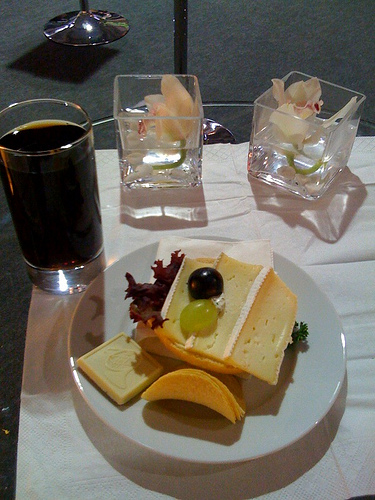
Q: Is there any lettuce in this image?
A: Yes, there is lettuce.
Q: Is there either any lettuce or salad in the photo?
A: Yes, there is lettuce.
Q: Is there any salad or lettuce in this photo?
A: Yes, there is lettuce.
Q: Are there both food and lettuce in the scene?
A: Yes, there are both lettuce and food.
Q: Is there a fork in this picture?
A: No, there are no forks.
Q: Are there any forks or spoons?
A: No, there are no forks or spoons.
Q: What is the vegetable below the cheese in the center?
A: The vegetable is lettuce.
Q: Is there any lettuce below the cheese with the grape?
A: Yes, there is lettuce below the cheese.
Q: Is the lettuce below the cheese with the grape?
A: Yes, the lettuce is below the cheese.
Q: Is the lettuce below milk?
A: No, the lettuce is below the cheese.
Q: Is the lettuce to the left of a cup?
A: No, the lettuce is to the left of the grape.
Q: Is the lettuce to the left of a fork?
A: No, the lettuce is to the left of the grape.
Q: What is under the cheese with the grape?
A: The lettuce is under the cheese.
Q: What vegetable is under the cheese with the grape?
A: The vegetable is lettuce.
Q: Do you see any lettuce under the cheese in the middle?
A: Yes, there is lettuce under the cheese.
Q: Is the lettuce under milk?
A: No, the lettuce is under the cheese.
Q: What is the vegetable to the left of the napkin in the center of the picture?
A: The vegetable is lettuce.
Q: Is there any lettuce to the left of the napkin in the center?
A: Yes, there is lettuce to the left of the napkin.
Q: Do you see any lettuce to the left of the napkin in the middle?
A: Yes, there is lettuce to the left of the napkin.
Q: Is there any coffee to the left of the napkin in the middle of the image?
A: No, there is lettuce to the left of the napkin.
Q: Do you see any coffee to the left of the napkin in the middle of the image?
A: No, there is lettuce to the left of the napkin.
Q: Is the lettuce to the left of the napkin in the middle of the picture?
A: Yes, the lettuce is to the left of the napkin.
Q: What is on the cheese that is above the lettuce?
A: The grape is on the cheese.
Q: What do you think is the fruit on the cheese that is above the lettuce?
A: The fruit is a grape.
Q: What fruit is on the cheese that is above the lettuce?
A: The fruit is a grape.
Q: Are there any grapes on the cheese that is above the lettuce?
A: Yes, there is a grape on the cheese.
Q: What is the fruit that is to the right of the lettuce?
A: The fruit is a grape.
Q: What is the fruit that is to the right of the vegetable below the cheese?
A: The fruit is a grape.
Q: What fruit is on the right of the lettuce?
A: The fruit is a grape.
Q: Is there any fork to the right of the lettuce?
A: No, there is a grape to the right of the lettuce.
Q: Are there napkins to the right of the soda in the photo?
A: Yes, there is a napkin to the right of the soda.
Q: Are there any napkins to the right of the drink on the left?
A: Yes, there is a napkin to the right of the soda.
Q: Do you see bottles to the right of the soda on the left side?
A: No, there is a napkin to the right of the soda.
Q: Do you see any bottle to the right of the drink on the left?
A: No, there is a napkin to the right of the soda.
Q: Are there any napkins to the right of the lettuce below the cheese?
A: Yes, there is a napkin to the right of the lettuce.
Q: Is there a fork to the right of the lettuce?
A: No, there is a napkin to the right of the lettuce.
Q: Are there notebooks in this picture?
A: No, there are no notebooks.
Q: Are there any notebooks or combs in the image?
A: No, there are no notebooks or combs.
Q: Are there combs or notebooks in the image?
A: No, there are no notebooks or combs.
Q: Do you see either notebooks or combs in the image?
A: No, there are no notebooks or combs.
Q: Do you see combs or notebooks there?
A: No, there are no notebooks or combs.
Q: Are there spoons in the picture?
A: No, there are no spoons.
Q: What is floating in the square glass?
A: The flower is floating in the glass.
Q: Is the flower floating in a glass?
A: Yes, the flower is floating in a glass.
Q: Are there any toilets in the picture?
A: No, there are no toilets.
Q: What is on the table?
A: The napkin is on the table.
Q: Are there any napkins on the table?
A: Yes, there is a napkin on the table.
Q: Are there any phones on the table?
A: No, there is a napkin on the table.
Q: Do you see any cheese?
A: Yes, there is cheese.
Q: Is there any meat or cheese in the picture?
A: Yes, there is cheese.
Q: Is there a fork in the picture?
A: No, there are no forks.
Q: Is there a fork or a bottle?
A: No, there are no forks or bottles.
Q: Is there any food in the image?
A: Yes, there is food.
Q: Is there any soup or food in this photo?
A: Yes, there is food.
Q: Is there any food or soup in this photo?
A: Yes, there is food.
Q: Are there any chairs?
A: No, there are no chairs.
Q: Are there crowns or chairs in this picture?
A: No, there are no chairs or crowns.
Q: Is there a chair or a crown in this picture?
A: No, there are no chairs or crowns.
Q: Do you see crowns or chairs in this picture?
A: No, there are no chairs or crowns.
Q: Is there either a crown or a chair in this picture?
A: No, there are no chairs or crowns.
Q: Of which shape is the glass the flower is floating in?
A: The glass is square.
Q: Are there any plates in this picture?
A: Yes, there is a plate.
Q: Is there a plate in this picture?
A: Yes, there is a plate.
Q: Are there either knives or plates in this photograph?
A: Yes, there is a plate.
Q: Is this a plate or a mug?
A: This is a plate.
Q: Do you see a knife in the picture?
A: No, there are no knives.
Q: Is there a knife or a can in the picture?
A: No, there are no knives or cans.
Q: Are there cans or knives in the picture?
A: No, there are no knives or cans.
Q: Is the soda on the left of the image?
A: Yes, the soda is on the left of the image.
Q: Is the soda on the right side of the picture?
A: No, the soda is on the left of the image.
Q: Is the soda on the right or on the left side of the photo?
A: The soda is on the left of the image.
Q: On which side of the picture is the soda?
A: The soda is on the left of the image.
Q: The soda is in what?
A: The soda is in the glass.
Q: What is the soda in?
A: The soda is in the glass.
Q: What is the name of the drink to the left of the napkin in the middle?
A: The drink is soda.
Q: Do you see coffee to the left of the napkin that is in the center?
A: No, there is soda to the left of the napkin.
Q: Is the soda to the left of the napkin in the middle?
A: Yes, the soda is to the left of the napkin.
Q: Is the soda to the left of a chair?
A: No, the soda is to the left of the napkin.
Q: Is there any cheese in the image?
A: Yes, there is cheese.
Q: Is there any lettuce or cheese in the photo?
A: Yes, there is cheese.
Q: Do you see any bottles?
A: No, there are no bottles.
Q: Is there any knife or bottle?
A: No, there are no bottles or knives.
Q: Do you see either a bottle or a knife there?
A: No, there are no bottles or knives.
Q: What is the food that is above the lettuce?
A: The food is cheese.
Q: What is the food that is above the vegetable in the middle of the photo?
A: The food is cheese.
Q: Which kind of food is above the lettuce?
A: The food is cheese.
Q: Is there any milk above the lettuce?
A: No, there is cheese above the lettuce.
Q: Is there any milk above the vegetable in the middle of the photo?
A: No, there is cheese above the lettuce.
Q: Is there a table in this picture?
A: Yes, there is a table.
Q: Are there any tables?
A: Yes, there is a table.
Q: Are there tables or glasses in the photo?
A: Yes, there is a table.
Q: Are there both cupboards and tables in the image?
A: No, there is a table but no cupboards.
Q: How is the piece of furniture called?
A: The piece of furniture is a table.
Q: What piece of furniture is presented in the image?
A: The piece of furniture is a table.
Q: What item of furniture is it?
A: The piece of furniture is a table.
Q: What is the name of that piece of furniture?
A: That is a table.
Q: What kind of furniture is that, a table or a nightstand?
A: That is a table.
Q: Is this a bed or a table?
A: This is a table.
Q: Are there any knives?
A: No, there are no knives.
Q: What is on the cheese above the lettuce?
A: The grape is on the cheese.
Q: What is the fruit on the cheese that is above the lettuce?
A: The fruit is a grape.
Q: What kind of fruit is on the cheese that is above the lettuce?
A: The fruit is a grape.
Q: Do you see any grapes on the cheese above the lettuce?
A: Yes, there is a grape on the cheese.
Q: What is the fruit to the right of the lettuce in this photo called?
A: The fruit is a grape.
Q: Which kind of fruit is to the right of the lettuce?
A: The fruit is a grape.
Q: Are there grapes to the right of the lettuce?
A: Yes, there is a grape to the right of the lettuce.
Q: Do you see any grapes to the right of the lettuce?
A: Yes, there is a grape to the right of the lettuce.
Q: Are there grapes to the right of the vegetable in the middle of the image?
A: Yes, there is a grape to the right of the lettuce.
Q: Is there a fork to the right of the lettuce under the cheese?
A: No, there is a grape to the right of the lettuce.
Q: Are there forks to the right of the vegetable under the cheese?
A: No, there is a grape to the right of the lettuce.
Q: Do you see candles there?
A: No, there are no candles.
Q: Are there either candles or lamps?
A: No, there are no candles or lamps.